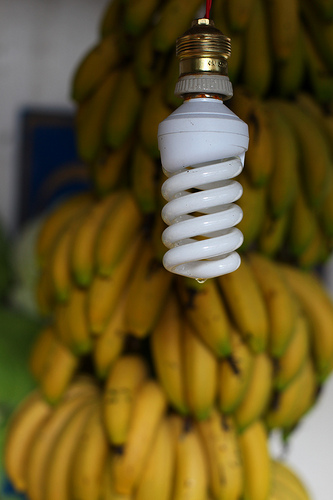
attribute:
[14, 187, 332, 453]
bananas — ripe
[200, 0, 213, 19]
red wire — above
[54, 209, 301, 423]
bananas bulb — hanging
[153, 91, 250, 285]
light bulb — white, twisted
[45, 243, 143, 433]
banana — yellow, single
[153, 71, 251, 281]
bulb — white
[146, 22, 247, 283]
light — hanging, white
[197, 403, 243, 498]
banana — single, yellow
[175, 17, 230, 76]
light socket — metal, gold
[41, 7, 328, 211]
bananas — hanging up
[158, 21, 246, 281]
light bulb — hanging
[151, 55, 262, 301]
bulb — coiled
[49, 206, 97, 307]
banana — yellow, single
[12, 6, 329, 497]
bananas — ripe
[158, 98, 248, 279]
bulb — glass, plastic, white